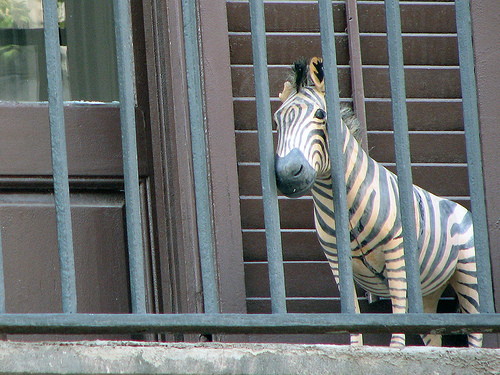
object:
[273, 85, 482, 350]
stripes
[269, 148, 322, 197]
nose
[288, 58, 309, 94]
mane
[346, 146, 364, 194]
stripes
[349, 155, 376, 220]
stripes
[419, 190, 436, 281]
stripes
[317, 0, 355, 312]
bar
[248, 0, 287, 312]
bar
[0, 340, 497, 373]
balcony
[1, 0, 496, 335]
fence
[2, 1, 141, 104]
window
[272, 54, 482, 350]
zebra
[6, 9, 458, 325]
bars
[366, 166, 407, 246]
stripe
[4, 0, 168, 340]
door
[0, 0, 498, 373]
cage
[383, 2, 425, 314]
bar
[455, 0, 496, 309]
bar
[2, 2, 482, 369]
outside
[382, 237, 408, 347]
leg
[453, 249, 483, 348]
leg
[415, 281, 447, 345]
leg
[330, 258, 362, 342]
leg